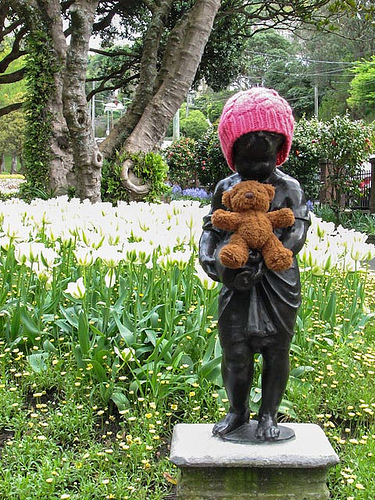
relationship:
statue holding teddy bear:
[199, 86, 310, 444] [210, 182, 295, 272]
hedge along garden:
[310, 204, 373, 240] [0, 0, 374, 500]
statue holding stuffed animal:
[199, 86, 310, 444] [210, 182, 295, 272]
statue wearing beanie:
[199, 86, 310, 444] [217, 88, 296, 173]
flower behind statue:
[196, 190, 207, 199] [199, 86, 310, 444]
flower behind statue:
[178, 232, 192, 244] [199, 86, 310, 444]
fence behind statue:
[336, 169, 372, 208] [199, 86, 310, 444]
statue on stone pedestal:
[199, 86, 310, 444] [171, 419, 340, 499]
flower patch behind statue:
[0, 193, 373, 312] [199, 86, 310, 444]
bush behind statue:
[169, 139, 198, 186] [199, 86, 310, 444]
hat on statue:
[217, 88, 296, 173] [199, 86, 310, 444]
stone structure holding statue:
[171, 419, 340, 499] [199, 86, 310, 444]